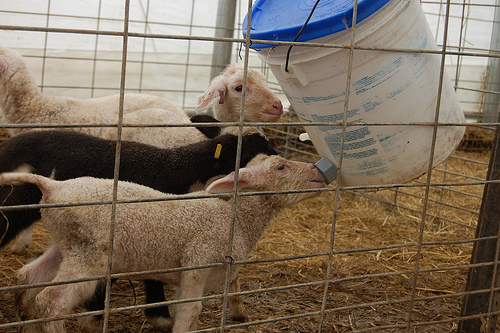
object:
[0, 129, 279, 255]
sheep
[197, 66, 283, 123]
sheep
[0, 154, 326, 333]
lambs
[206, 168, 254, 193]
ear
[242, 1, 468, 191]
container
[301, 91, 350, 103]
writing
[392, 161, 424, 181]
smudges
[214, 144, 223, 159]
tag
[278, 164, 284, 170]
eye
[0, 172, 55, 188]
tail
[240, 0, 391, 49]
lid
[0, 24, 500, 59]
bars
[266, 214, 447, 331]
hay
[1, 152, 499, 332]
floor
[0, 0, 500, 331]
cage